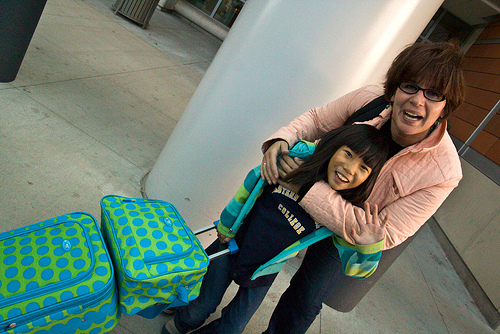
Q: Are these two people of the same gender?
A: Yes, all the people are female.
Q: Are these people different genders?
A: No, all the people are female.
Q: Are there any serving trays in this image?
A: No, there are no serving trays.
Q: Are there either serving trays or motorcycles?
A: No, there are no serving trays or motorcycles.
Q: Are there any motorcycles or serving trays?
A: No, there are no serving trays or motorcycles.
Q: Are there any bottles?
A: No, there are no bottles.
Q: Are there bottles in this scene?
A: No, there are no bottles.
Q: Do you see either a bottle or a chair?
A: No, there are no bottles or chairs.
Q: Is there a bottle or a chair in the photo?
A: No, there are no bottles or chairs.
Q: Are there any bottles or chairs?
A: No, there are no bottles or chairs.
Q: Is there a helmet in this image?
A: No, there are no helmets.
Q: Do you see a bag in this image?
A: Yes, there is a bag.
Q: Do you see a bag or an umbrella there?
A: Yes, there is a bag.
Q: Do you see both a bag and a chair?
A: No, there is a bag but no chairs.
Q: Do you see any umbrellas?
A: No, there are no umbrellas.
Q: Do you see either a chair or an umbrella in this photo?
A: No, there are no umbrellas or chairs.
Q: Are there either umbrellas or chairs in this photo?
A: No, there are no umbrellas or chairs.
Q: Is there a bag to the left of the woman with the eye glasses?
A: Yes, there is a bag to the left of the woman.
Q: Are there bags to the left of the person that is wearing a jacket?
A: Yes, there is a bag to the left of the woman.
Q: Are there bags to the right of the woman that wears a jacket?
A: No, the bag is to the left of the woman.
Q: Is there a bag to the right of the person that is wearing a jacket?
A: No, the bag is to the left of the woman.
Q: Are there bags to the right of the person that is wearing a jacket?
A: No, the bag is to the left of the woman.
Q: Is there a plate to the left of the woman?
A: No, there is a bag to the left of the woman.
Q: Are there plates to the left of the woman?
A: No, there is a bag to the left of the woman.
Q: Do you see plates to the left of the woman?
A: No, there is a bag to the left of the woman.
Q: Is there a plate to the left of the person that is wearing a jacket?
A: No, there is a bag to the left of the woman.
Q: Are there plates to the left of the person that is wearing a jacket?
A: No, there is a bag to the left of the woman.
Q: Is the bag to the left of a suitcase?
A: No, the bag is to the left of a woman.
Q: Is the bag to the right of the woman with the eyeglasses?
A: No, the bag is to the left of the woman.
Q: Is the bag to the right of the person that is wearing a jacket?
A: No, the bag is to the left of the woman.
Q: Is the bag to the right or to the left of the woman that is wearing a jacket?
A: The bag is to the left of the woman.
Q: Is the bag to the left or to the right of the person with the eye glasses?
A: The bag is to the left of the woman.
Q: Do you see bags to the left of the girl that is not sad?
A: Yes, there is a bag to the left of the girl.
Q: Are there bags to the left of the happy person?
A: Yes, there is a bag to the left of the girl.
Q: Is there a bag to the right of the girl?
A: No, the bag is to the left of the girl.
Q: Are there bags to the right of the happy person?
A: No, the bag is to the left of the girl.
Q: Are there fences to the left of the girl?
A: No, there is a bag to the left of the girl.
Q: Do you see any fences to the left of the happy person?
A: No, there is a bag to the left of the girl.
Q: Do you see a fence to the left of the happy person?
A: No, there is a bag to the left of the girl.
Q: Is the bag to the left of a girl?
A: Yes, the bag is to the left of a girl.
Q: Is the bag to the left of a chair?
A: No, the bag is to the left of a girl.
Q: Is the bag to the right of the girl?
A: No, the bag is to the left of the girl.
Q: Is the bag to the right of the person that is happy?
A: No, the bag is to the left of the girl.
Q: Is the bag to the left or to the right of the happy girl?
A: The bag is to the left of the girl.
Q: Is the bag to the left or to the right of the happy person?
A: The bag is to the left of the girl.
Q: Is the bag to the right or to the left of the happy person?
A: The bag is to the left of the girl.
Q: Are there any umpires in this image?
A: No, there are no umpires.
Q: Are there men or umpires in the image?
A: No, there are no umpires or men.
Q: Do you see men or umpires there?
A: No, there are no umpires or men.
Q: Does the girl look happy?
A: Yes, the girl is happy.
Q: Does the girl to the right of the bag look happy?
A: Yes, the girl is happy.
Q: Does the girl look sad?
A: No, the girl is happy.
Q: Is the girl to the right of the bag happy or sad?
A: The girl is happy.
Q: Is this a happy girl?
A: Yes, this is a happy girl.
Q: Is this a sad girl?
A: No, this is a happy girl.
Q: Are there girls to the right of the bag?
A: Yes, there is a girl to the right of the bag.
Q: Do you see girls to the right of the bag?
A: Yes, there is a girl to the right of the bag.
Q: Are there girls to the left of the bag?
A: No, the girl is to the right of the bag.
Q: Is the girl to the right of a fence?
A: No, the girl is to the right of the bag.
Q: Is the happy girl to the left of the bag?
A: No, the girl is to the right of the bag.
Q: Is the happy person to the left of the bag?
A: No, the girl is to the right of the bag.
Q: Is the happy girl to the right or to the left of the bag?
A: The girl is to the right of the bag.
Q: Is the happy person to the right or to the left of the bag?
A: The girl is to the right of the bag.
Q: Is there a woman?
A: Yes, there is a woman.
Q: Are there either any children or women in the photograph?
A: Yes, there is a woman.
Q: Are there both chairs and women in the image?
A: No, there is a woman but no chairs.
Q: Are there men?
A: No, there are no men.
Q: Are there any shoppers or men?
A: No, there are no men or shoppers.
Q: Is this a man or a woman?
A: This is a woman.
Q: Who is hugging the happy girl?
A: The woman is hugging the girl.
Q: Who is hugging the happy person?
A: The woman is hugging the girl.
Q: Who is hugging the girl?
A: The woman is hugging the girl.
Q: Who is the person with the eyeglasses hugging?
A: The woman is hugging the girl.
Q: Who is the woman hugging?
A: The woman is hugging the girl.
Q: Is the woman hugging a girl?
A: Yes, the woman is hugging a girl.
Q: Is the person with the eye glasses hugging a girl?
A: Yes, the woman is hugging a girl.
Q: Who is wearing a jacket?
A: The woman is wearing a jacket.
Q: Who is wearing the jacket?
A: The woman is wearing a jacket.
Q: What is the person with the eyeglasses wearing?
A: The woman is wearing a jacket.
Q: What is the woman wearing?
A: The woman is wearing a jacket.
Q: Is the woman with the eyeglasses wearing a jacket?
A: Yes, the woman is wearing a jacket.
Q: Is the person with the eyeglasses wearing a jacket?
A: Yes, the woman is wearing a jacket.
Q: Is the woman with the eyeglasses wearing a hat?
A: No, the woman is wearing a jacket.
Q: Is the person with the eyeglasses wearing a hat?
A: No, the woman is wearing a jacket.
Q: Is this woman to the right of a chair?
A: No, the woman is to the right of the bag.